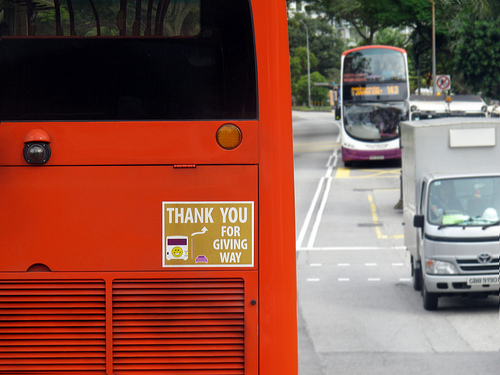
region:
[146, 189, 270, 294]
Sign on a bus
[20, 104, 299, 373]
Orange back to a bus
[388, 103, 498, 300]
Silver truck on a road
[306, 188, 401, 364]
White lines on a street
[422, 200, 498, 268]
Wipers on a truck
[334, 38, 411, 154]
Front of a bus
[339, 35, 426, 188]
Orange, white and purple bus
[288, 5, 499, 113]
Green trees by a road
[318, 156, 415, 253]
Yellow line on a road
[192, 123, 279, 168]
Light on a bus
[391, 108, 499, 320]
Truck running in the road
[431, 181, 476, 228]
Person in front sit of car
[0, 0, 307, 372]
Rear of red bus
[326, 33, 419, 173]
Double decker bus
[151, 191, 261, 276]
Red bus has a sticker on rear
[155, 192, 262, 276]
Sticker has white letters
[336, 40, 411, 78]
Roof of rear bus is red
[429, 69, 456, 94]
Sign on right side of street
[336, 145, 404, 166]
Bumper of bus is purple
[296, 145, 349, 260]
White lines on road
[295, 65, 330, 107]
a tree in a distance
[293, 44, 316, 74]
a tree in a distance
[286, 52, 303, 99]
a tree in a distance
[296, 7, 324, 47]
a tree in a distance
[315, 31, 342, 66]
a tree in a distance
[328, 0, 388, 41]
a tree in a distance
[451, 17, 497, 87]
a tree in a distance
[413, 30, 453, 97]
a tree in a distance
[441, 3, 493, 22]
a tree in a distance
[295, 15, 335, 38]
a tree in a distance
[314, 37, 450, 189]
double decker bus driving down the street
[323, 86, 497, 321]
truck van riding down the street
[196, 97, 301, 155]
yellow lights on the back of a orange bus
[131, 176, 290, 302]
the letter t on the back of a orange bus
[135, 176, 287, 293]
the letter h on the back of a orange bus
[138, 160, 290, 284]
the letter a on the back of a orange bus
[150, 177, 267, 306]
the letter n on the back of a orange bus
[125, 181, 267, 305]
the letter k on the back of a orange bus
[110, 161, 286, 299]
the letter y on the back of a orange bus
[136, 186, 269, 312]
the letter o on the back of a orange bus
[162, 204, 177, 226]
a letter is written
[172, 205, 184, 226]
a letter is written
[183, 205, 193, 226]
a letter is written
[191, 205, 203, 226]
a letter is written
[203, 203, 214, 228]
a letter is written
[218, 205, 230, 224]
a letter is written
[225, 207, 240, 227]
a letter is written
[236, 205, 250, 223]
a letter is written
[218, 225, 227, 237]
a letter is written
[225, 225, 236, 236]
a letter is written